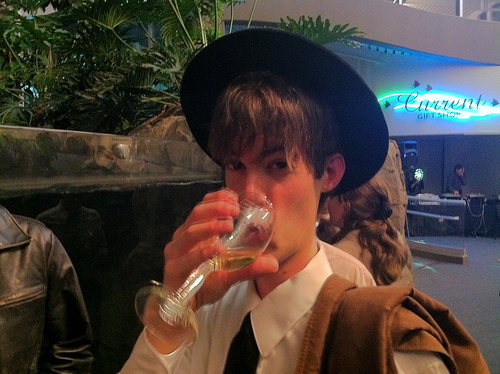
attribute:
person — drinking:
[109, 28, 396, 373]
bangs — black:
[205, 116, 310, 175]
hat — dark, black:
[167, 27, 392, 201]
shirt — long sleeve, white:
[102, 241, 334, 374]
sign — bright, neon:
[372, 76, 499, 129]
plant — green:
[268, 11, 371, 52]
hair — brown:
[204, 68, 347, 176]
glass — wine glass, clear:
[125, 188, 276, 350]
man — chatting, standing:
[439, 162, 468, 196]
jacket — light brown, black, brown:
[288, 264, 493, 373]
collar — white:
[212, 238, 334, 360]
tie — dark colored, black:
[213, 310, 264, 374]